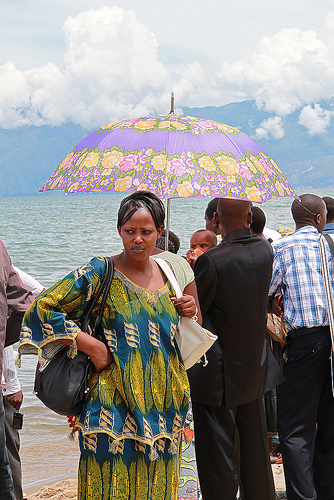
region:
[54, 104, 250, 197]
umbrella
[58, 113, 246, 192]
purple yellow and pink umbrella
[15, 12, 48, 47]
white clouds in blue sky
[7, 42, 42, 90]
white clouds in blue sky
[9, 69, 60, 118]
white clouds in blue sky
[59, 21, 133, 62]
white clouds in blue sky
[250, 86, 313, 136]
white clouds in blue sky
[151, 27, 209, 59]
white clouds in blue sky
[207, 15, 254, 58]
white clouds in blue sky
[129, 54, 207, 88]
white clouds in blue sky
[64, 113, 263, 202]
open purple umbrella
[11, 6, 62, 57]
white clouds in blue sky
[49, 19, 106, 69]
white clouds in blue sky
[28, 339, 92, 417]
black purse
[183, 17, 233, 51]
white clouds in blue sky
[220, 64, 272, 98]
white clouds in blue sky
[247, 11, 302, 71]
white clouds in blue sky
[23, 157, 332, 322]
a crowd of people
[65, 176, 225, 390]
this woman looks unhappy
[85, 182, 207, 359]
she might be upset with someone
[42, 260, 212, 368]
her hand is on her hip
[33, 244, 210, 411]
she is holding two purses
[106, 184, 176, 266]
her hair is neatly styled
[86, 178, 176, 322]
she is a pretty woman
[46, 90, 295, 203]
this is a light purple umbrella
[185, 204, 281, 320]
people at an event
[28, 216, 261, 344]
this event is by the water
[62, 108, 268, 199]
colorful umbrella held by woman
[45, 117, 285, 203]
open umbrella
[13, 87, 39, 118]
white clouds in blue sky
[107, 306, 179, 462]
dress worn by woman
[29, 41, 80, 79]
white clouds in blue sky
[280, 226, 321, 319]
blue and white shirt worn by man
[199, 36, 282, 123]
white clouds in blue sky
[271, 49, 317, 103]
white clouds in blue sky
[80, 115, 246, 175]
floral colored umbrella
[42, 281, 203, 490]
blue and green african dress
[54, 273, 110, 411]
black leather handbag held by woman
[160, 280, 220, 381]
cream colored leather purse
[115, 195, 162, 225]
woman with short black hair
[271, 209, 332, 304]
blue and white plaid shirt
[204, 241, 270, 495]
black tuxedo suit on man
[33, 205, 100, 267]
ocean in front of crowd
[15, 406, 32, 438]
black digital camera in man's hand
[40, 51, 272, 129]
puffy clouds above the ocean